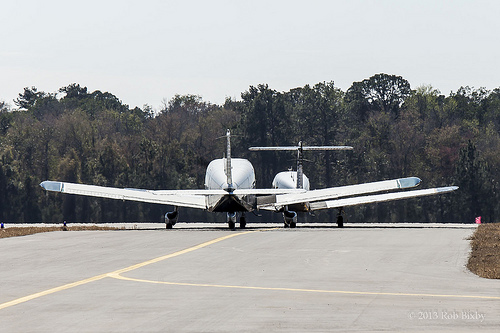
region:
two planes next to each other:
[38, 75, 465, 285]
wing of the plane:
[33, 148, 205, 241]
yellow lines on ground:
[64, 244, 161, 326]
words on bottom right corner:
[401, 291, 492, 331]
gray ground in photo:
[266, 236, 346, 283]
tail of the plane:
[201, 147, 258, 223]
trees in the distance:
[130, 76, 359, 144]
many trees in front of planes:
[71, 54, 436, 176]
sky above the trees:
[117, 2, 276, 77]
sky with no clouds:
[121, 12, 277, 77]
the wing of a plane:
[38, 173, 206, 215]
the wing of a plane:
[268, 170, 425, 202]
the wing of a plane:
[311, 189, 461, 216]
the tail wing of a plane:
[247, 139, 360, 158]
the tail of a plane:
[218, 126, 239, 192]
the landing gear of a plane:
[156, 209, 179, 232]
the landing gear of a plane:
[223, 208, 239, 234]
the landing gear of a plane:
[237, 212, 249, 229]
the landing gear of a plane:
[280, 210, 299, 228]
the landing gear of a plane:
[328, 209, 350, 230]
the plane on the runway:
[27, 154, 440, 243]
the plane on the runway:
[237, 133, 450, 232]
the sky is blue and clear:
[1, 3, 498, 96]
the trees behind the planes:
[14, 87, 496, 199]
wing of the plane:
[291, 173, 417, 200]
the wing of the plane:
[300, 181, 459, 218]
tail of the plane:
[166, 158, 293, 215]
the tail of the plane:
[248, 128, 355, 189]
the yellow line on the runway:
[10, 229, 244, 319]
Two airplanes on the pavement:
[27, 121, 465, 237]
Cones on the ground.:
[469, 210, 485, 227]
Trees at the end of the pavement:
[0, 78, 497, 218]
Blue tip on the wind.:
[32, 175, 67, 200]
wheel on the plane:
[160, 203, 182, 230]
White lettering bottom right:
[405, 300, 486, 331]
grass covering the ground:
[467, 216, 498, 283]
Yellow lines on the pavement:
[1, 233, 491, 318]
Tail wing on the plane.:
[217, 125, 244, 192]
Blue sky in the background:
[1, 0, 493, 108]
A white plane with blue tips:
[31, 121, 459, 258]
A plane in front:
[261, 137, 458, 235]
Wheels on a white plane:
[164, 211, 261, 247]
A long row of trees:
[33, 84, 473, 216]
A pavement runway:
[63, 238, 443, 308]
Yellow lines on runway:
[33, 247, 436, 314]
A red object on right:
[462, 206, 492, 231]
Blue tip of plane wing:
[30, 176, 75, 203]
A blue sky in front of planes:
[47, 20, 483, 76]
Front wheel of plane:
[218, 210, 245, 237]